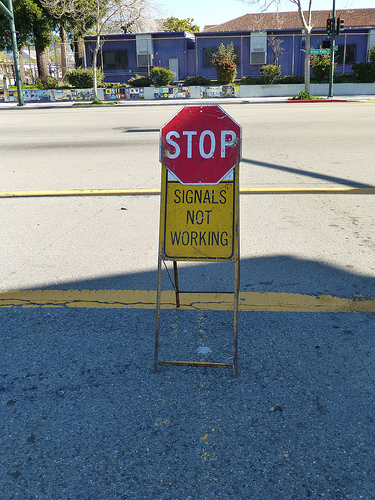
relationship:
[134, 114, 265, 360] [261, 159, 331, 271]
sign on street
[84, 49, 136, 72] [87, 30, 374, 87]
window on house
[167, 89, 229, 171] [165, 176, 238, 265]
sign over yellow & black sign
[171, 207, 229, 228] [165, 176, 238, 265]
word on yellow & black sign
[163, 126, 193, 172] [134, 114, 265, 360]
letter on sign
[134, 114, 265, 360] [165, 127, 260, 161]
sign says stop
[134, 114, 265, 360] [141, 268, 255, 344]
sign on stand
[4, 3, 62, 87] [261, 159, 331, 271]
tree by street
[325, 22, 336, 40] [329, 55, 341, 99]
traffic signal on traffic pole